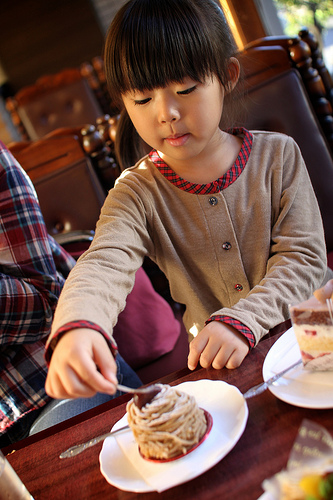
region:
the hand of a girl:
[40, 329, 124, 402]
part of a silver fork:
[53, 426, 130, 457]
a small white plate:
[96, 377, 249, 493]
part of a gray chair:
[18, 354, 139, 444]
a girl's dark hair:
[97, 0, 239, 112]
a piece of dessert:
[290, 297, 332, 369]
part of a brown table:
[1, 324, 330, 499]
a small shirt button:
[207, 196, 221, 208]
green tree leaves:
[277, 2, 331, 32]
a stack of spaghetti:
[120, 385, 208, 456]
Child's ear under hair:
[218, 52, 238, 91]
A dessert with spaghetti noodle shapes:
[115, 379, 210, 458]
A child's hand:
[181, 313, 246, 368]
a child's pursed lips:
[159, 126, 191, 143]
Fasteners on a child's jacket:
[202, 192, 217, 203]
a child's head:
[105, 0, 238, 163]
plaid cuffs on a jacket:
[201, 299, 257, 345]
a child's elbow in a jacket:
[265, 229, 325, 282]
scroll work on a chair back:
[284, 36, 326, 123]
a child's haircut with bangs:
[105, 67, 226, 93]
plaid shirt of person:
[2, 140, 94, 422]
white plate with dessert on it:
[98, 374, 235, 495]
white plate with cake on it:
[261, 272, 332, 412]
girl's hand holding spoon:
[39, 336, 150, 401]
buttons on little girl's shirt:
[205, 193, 244, 300]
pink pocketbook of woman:
[51, 221, 175, 362]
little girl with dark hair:
[25, 3, 320, 380]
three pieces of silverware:
[37, 356, 311, 462]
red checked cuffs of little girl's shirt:
[39, 312, 256, 343]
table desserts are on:
[4, 354, 331, 499]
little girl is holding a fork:
[25, 313, 206, 497]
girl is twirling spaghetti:
[87, 348, 210, 447]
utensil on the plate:
[40, 398, 173, 482]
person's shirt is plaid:
[0, 138, 112, 438]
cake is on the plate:
[263, 269, 331, 389]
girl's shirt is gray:
[72, 122, 323, 349]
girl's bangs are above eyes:
[99, 15, 245, 94]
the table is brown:
[5, 321, 332, 495]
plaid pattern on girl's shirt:
[134, 145, 265, 207]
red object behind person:
[63, 234, 225, 411]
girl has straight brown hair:
[96, 2, 232, 87]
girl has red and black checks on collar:
[150, 137, 259, 209]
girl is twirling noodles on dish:
[112, 349, 210, 467]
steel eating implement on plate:
[61, 421, 184, 460]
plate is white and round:
[103, 369, 241, 485]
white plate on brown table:
[100, 377, 226, 479]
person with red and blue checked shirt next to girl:
[2, 143, 50, 410]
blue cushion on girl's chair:
[196, 64, 331, 161]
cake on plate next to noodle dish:
[248, 292, 321, 407]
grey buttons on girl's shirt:
[207, 198, 246, 314]